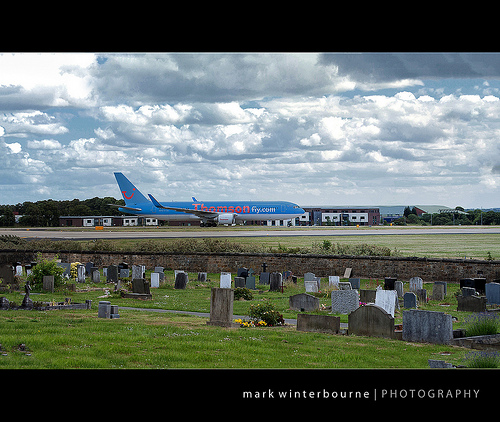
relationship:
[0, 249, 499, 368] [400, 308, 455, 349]
cemetery with headstone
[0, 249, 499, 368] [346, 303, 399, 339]
cemetery with headstone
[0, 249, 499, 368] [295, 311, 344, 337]
cemetery with headstone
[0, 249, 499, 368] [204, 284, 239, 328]
cemetery with headstone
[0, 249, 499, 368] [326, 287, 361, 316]
cemetery with headstone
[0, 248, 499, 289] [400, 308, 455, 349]
wall behind headstone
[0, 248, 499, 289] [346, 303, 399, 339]
wall behind headstone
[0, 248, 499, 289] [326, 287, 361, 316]
wall behind headstone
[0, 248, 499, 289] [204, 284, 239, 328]
wall behind headstone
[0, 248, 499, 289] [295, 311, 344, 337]
wall behind headstone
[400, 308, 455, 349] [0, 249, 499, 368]
headstone in cemetery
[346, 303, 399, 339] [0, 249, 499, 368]
headstone in cemetery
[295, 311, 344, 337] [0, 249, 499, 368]
headstone in cemetery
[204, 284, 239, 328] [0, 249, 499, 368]
headstone in cemetery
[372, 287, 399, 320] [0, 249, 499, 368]
headstone in cemetery